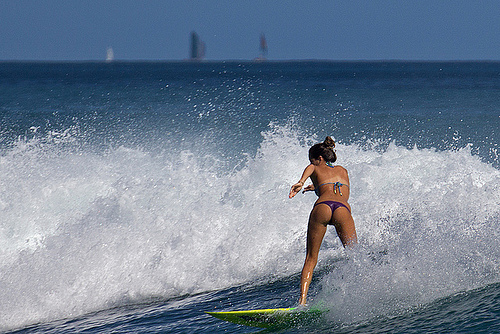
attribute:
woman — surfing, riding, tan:
[288, 134, 368, 309]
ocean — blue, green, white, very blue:
[0, 54, 500, 333]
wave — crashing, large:
[9, 132, 493, 304]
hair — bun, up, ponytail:
[309, 143, 335, 157]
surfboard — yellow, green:
[195, 299, 347, 326]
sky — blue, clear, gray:
[1, 1, 499, 58]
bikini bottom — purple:
[313, 200, 353, 228]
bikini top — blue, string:
[315, 157, 349, 193]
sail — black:
[192, 32, 198, 52]